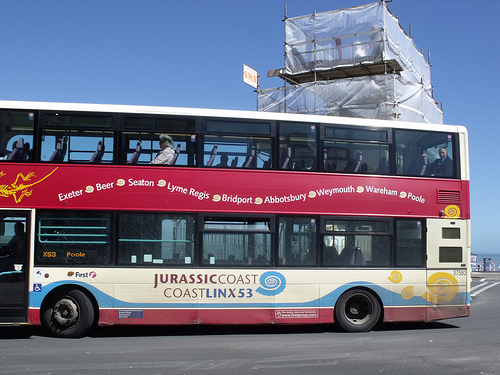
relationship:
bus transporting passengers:
[1, 100, 472, 337] [1, 108, 462, 179]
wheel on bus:
[40, 287, 96, 339] [1, 100, 472, 337]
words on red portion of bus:
[57, 177, 427, 208] [0, 163, 469, 218]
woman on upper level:
[152, 135, 176, 165] [2, 100, 470, 200]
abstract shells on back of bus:
[387, 271, 459, 304] [370, 119, 471, 329]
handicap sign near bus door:
[34, 284, 43, 292] [0, 210, 33, 327]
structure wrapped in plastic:
[257, 0, 443, 125] [284, 1, 385, 77]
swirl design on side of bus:
[259, 270, 286, 298] [1, 100, 472, 337]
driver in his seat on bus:
[1, 221, 25, 274] [1, 100, 472, 337]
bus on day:
[1, 100, 472, 337] [1, 0, 500, 128]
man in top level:
[421, 148, 454, 178] [2, 100, 470, 200]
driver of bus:
[1, 221, 25, 274] [1, 100, 472, 337]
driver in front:
[1, 221, 25, 274] [1, 101, 114, 352]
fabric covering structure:
[284, 1, 385, 77] [257, 0, 443, 125]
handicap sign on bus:
[34, 284, 43, 292] [1, 100, 472, 337]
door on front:
[0, 210, 33, 327] [1, 101, 114, 352]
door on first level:
[0, 210, 33, 327] [1, 187, 472, 336]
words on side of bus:
[153, 275, 258, 290] [1, 100, 470, 326]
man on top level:
[421, 148, 454, 178] [2, 100, 470, 200]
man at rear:
[421, 148, 454, 178] [370, 119, 471, 329]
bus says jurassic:
[1, 100, 472, 337] [155, 274, 219, 287]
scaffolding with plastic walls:
[257, 0, 443, 125] [286, 0, 432, 94]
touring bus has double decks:
[1, 100, 472, 337] [1, 100, 471, 283]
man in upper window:
[152, 135, 176, 165] [119, 112, 202, 171]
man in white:
[152, 135, 176, 165] [151, 148, 176, 166]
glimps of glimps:
[470, 252, 499, 273] [470, 252, 499, 273]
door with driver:
[0, 210, 33, 327] [1, 221, 25, 274]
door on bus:
[0, 210, 33, 327] [1, 100, 472, 337]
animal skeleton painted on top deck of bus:
[0, 163, 59, 209] [2, 100, 470, 200]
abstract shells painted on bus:
[389, 271, 459, 307] [1, 100, 472, 337]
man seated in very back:
[421, 148, 454, 178] [370, 119, 471, 329]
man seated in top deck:
[432, 148, 459, 180] [2, 100, 470, 200]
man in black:
[432, 148, 459, 180] [433, 158, 456, 179]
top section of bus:
[2, 100, 470, 200] [1, 100, 472, 337]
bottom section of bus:
[1, 187, 472, 336] [1, 100, 472, 337]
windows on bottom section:
[36, 209, 427, 270] [1, 187, 472, 336]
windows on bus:
[36, 209, 427, 270] [1, 100, 472, 337]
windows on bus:
[1, 108, 461, 180] [1, 100, 472, 337]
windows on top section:
[1, 108, 461, 180] [2, 100, 470, 200]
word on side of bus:
[153, 275, 258, 290] [1, 100, 470, 326]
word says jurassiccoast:
[153, 275, 258, 290] [153, 273, 259, 288]